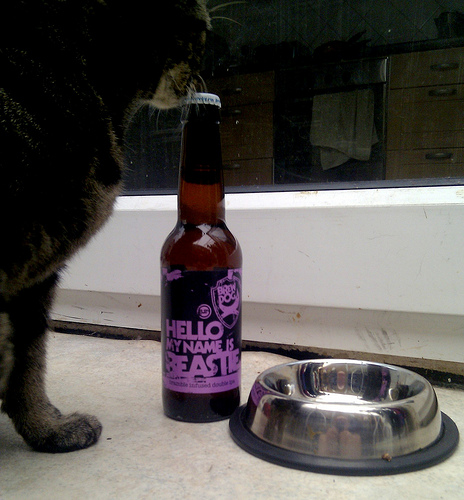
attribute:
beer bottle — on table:
[159, 86, 247, 424]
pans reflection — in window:
[309, 27, 370, 49]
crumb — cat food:
[381, 447, 395, 464]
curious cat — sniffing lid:
[1, 2, 223, 461]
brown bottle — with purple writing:
[155, 91, 246, 422]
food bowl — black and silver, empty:
[228, 357, 449, 475]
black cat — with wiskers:
[3, 1, 223, 453]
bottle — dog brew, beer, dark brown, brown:
[155, 90, 246, 429]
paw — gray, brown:
[19, 397, 106, 454]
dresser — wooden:
[380, 39, 461, 175]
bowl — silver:
[231, 355, 459, 479]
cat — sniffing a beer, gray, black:
[1, 4, 216, 455]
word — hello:
[161, 320, 224, 345]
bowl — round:
[239, 355, 454, 459]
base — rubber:
[223, 399, 459, 474]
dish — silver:
[226, 353, 456, 477]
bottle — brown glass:
[159, 88, 250, 424]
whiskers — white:
[173, 70, 205, 124]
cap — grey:
[184, 85, 223, 113]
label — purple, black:
[155, 260, 246, 396]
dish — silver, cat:
[246, 354, 446, 467]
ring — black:
[227, 397, 462, 479]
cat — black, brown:
[0, 5, 186, 455]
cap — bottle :
[179, 87, 228, 104]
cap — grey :
[180, 89, 227, 108]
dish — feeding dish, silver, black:
[201, 334, 459, 493]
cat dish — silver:
[215, 347, 458, 498]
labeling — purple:
[134, 253, 256, 425]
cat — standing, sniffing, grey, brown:
[8, 7, 205, 447]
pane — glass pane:
[101, 10, 457, 189]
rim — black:
[256, 435, 393, 498]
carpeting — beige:
[16, 330, 258, 492]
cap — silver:
[160, 64, 235, 127]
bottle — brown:
[153, 78, 261, 446]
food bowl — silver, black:
[231, 318, 452, 497]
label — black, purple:
[139, 283, 247, 385]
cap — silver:
[169, 73, 235, 115]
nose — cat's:
[167, 1, 229, 57]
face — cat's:
[64, 3, 242, 137]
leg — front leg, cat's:
[10, 356, 124, 490]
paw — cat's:
[20, 377, 122, 464]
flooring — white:
[43, 348, 380, 497]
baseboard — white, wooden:
[86, 184, 461, 313]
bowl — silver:
[241, 336, 445, 489]